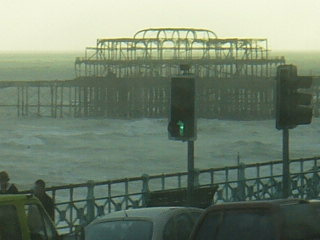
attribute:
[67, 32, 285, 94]
structure — large, open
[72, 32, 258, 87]
building — framework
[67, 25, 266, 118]
building — levels, different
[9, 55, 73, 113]
extension — building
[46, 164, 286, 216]
railing — metal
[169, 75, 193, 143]
light — green, traffic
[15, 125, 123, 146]
waves — low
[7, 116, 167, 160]
water — surface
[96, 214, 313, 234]
cars — different colors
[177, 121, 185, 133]
light — green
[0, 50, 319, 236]
water — choppy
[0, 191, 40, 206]
roof — yellow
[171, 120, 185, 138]
light — green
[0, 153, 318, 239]
railing — metal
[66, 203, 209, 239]
car — white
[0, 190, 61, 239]
car — green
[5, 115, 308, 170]
sea — blue , grey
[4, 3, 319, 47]
sky — yellow, grey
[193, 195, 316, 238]
car — red, black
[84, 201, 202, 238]
car — grey, yellow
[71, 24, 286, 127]
construction — unfinished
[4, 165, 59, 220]
people — walking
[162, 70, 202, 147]
traffic light — green